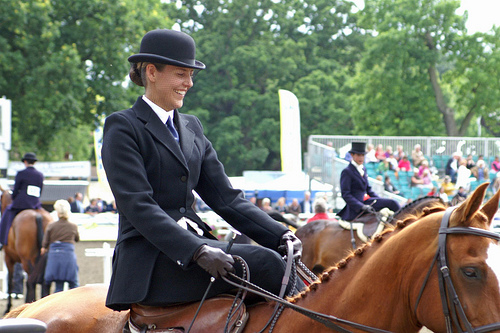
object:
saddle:
[122, 291, 253, 331]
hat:
[124, 28, 209, 71]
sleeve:
[95, 113, 206, 270]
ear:
[456, 175, 490, 222]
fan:
[298, 188, 311, 213]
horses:
[280, 186, 482, 273]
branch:
[428, 70, 483, 136]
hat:
[348, 141, 370, 155]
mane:
[285, 203, 449, 308]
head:
[135, 63, 198, 109]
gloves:
[193, 243, 237, 281]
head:
[351, 151, 365, 164]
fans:
[366, 144, 499, 195]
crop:
[184, 281, 214, 332]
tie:
[164, 115, 185, 144]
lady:
[66, 27, 311, 308]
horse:
[0, 182, 497, 331]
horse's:
[453, 255, 491, 284]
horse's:
[360, 289, 401, 320]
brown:
[393, 299, 405, 311]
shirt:
[92, 95, 297, 310]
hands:
[274, 226, 304, 263]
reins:
[225, 269, 355, 323]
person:
[42, 196, 81, 296]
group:
[59, 134, 497, 216]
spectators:
[249, 173, 341, 216]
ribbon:
[178, 57, 203, 69]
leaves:
[244, 29, 347, 70]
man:
[333, 140, 399, 221]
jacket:
[329, 163, 400, 221]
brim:
[125, 51, 208, 70]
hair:
[126, 59, 158, 88]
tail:
[34, 215, 50, 264]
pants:
[149, 242, 301, 305]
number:
[25, 185, 42, 198]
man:
[0, 149, 46, 246]